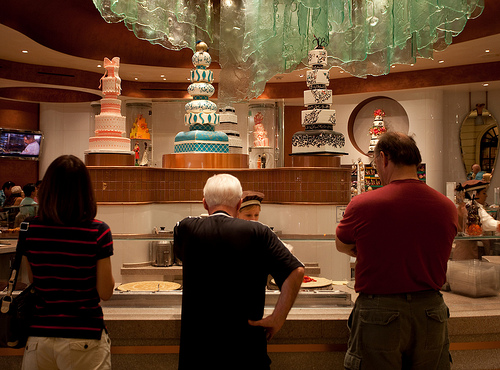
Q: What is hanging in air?
A: Decor.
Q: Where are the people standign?
A: Near table.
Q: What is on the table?
A: Cakes.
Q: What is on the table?
A: Cakes.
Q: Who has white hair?
A: The man in the middle.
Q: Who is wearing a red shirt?
A: The man on the right.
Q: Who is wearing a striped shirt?
A: The woman on the left.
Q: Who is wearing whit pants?
A: The woman on the left.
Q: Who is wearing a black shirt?
A: The man in the middle.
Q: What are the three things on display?
A: Cakes.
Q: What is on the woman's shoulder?
A: A handbag.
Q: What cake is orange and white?
A: The cake on the left.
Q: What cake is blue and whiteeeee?
A: The cake in the middle.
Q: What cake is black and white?
A: The cake on the right.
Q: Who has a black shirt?
A: The man.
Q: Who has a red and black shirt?
A: The woman.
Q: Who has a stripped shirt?
A: The woman.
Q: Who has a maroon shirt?
A: The man.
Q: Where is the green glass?
A: The ceiling.